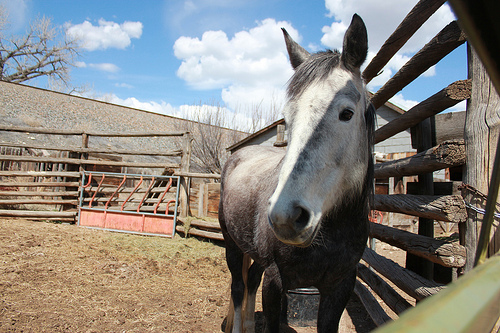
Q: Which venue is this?
A: This is a pen.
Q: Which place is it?
A: It is a pen.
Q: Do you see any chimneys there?
A: No, there are no chimneys.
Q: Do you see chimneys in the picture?
A: No, there are no chimneys.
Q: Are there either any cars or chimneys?
A: No, there are no chimneys or cars.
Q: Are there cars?
A: No, there are no cars.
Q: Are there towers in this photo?
A: No, there are no towers.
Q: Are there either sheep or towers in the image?
A: No, there are no towers or sheep.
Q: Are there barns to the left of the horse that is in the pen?
A: Yes, there is a barn to the left of the horse.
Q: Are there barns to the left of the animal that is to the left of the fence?
A: Yes, there is a barn to the left of the horse.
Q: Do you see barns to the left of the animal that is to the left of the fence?
A: Yes, there is a barn to the left of the horse.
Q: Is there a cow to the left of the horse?
A: No, there is a barn to the left of the horse.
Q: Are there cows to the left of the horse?
A: No, there is a barn to the left of the horse.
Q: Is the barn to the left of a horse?
A: Yes, the barn is to the left of a horse.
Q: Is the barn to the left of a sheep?
A: No, the barn is to the left of a horse.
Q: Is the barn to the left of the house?
A: Yes, the barn is to the left of the house.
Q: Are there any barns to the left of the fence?
A: Yes, there is a barn to the left of the fence.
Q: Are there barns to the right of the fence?
A: No, the barn is to the left of the fence.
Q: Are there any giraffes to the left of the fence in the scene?
A: No, there is a barn to the left of the fence.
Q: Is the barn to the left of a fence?
A: Yes, the barn is to the left of a fence.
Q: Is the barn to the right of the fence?
A: No, the barn is to the left of the fence.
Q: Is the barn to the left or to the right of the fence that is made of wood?
A: The barn is to the left of the fence.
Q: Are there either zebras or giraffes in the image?
A: No, there are no giraffes or zebras.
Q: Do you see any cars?
A: No, there are no cars.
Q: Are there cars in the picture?
A: No, there are no cars.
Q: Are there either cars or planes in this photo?
A: No, there are no cars or planes.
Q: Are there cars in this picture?
A: No, there are no cars.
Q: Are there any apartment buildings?
A: No, there are no apartment buildings.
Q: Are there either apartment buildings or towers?
A: No, there are no apartment buildings or towers.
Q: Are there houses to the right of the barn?
A: Yes, there is a house to the right of the barn.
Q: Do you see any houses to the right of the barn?
A: Yes, there is a house to the right of the barn.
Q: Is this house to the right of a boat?
A: No, the house is to the right of the barn.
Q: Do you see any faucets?
A: No, there are no faucets.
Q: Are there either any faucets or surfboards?
A: No, there are no faucets or surfboards.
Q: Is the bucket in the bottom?
A: Yes, the bucket is in the bottom of the image.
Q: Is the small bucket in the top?
A: No, the bucket is in the bottom of the image.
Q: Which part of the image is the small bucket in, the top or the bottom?
A: The bucket is in the bottom of the image.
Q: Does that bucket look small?
A: Yes, the bucket is small.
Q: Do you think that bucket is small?
A: Yes, the bucket is small.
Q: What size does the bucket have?
A: The bucket has small size.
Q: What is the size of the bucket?
A: The bucket is small.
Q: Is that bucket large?
A: No, the bucket is small.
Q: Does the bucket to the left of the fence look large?
A: No, the bucket is small.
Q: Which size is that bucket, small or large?
A: The bucket is small.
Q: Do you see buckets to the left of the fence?
A: Yes, there is a bucket to the left of the fence.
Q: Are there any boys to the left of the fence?
A: No, there is a bucket to the left of the fence.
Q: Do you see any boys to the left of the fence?
A: No, there is a bucket to the left of the fence.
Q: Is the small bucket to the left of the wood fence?
A: Yes, the bucket is to the left of the fence.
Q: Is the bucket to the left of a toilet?
A: No, the bucket is to the left of the fence.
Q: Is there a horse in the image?
A: Yes, there is a horse.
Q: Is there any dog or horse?
A: Yes, there is a horse.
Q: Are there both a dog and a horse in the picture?
A: No, there is a horse but no dogs.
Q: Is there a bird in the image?
A: No, there are no birds.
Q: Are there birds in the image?
A: No, there are no birds.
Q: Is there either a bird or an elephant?
A: No, there are no birds or elephants.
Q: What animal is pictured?
A: The animal is a horse.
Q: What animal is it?
A: The animal is a horse.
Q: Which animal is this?
A: That is a horse.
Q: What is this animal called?
A: That is a horse.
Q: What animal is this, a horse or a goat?
A: That is a horse.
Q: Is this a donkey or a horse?
A: This is a horse.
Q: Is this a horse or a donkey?
A: This is a horse.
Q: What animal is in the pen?
A: The horse is in the pen.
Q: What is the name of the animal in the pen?
A: The animal is a horse.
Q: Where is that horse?
A: The horse is in the pen.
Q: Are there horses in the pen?
A: Yes, there is a horse in the pen.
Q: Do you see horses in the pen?
A: Yes, there is a horse in the pen.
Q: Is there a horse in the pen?
A: Yes, there is a horse in the pen.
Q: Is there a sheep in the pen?
A: No, there is a horse in the pen.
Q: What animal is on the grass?
A: The horse is on the grass.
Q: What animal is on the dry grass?
A: The animal is a horse.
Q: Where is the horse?
A: The horse is on the grass.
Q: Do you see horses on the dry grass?
A: Yes, there is a horse on the grass.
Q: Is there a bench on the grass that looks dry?
A: No, there is a horse on the grass.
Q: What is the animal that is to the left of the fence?
A: The animal is a horse.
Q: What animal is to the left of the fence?
A: The animal is a horse.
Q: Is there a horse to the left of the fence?
A: Yes, there is a horse to the left of the fence.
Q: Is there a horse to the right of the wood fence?
A: No, the horse is to the left of the fence.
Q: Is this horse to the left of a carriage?
A: No, the horse is to the left of a fence.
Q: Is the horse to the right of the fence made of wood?
A: No, the horse is to the left of the fence.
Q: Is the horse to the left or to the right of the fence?
A: The horse is to the left of the fence.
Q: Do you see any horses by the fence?
A: Yes, there is a horse by the fence.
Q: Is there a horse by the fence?
A: Yes, there is a horse by the fence.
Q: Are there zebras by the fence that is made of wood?
A: No, there is a horse by the fence.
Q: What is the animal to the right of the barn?
A: The animal is a horse.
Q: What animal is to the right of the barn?
A: The animal is a horse.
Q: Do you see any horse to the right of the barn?
A: Yes, there is a horse to the right of the barn.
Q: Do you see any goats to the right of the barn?
A: No, there is a horse to the right of the barn.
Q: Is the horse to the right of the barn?
A: Yes, the horse is to the right of the barn.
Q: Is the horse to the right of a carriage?
A: No, the horse is to the right of the barn.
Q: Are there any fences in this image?
A: Yes, there is a fence.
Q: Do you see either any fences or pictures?
A: Yes, there is a fence.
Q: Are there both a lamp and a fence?
A: No, there is a fence but no lamps.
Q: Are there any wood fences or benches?
A: Yes, there is a wood fence.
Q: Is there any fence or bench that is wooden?
A: Yes, the fence is wooden.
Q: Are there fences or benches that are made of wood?
A: Yes, the fence is made of wood.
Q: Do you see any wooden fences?
A: Yes, there is a wood fence.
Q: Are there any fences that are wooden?
A: Yes, there is a fence that is wooden.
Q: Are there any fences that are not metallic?
A: Yes, there is a wooden fence.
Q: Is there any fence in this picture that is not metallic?
A: Yes, there is a wooden fence.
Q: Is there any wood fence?
A: Yes, there is a fence that is made of wood.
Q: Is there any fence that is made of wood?
A: Yes, there is a fence that is made of wood.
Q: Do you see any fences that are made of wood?
A: Yes, there is a fence that is made of wood.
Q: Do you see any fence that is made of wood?
A: Yes, there is a fence that is made of wood.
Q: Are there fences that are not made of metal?
A: Yes, there is a fence that is made of wood.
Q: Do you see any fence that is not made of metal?
A: Yes, there is a fence that is made of wood.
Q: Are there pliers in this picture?
A: No, there are no pliers.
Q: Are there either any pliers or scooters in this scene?
A: No, there are no pliers or scooters.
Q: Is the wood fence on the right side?
A: Yes, the fence is on the right of the image.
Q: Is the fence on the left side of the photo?
A: No, the fence is on the right of the image.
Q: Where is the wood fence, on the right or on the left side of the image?
A: The fence is on the right of the image.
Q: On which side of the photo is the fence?
A: The fence is on the right of the image.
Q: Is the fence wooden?
A: Yes, the fence is wooden.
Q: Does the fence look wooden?
A: Yes, the fence is wooden.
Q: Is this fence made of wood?
A: Yes, the fence is made of wood.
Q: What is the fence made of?
A: The fence is made of wood.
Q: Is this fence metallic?
A: No, the fence is wooden.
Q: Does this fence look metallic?
A: No, the fence is wooden.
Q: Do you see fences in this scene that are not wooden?
A: No, there is a fence but it is wooden.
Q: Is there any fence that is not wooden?
A: No, there is a fence but it is wooden.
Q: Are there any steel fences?
A: No, there is a fence but it is made of wood.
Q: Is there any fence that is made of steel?
A: No, there is a fence but it is made of wood.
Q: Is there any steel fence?
A: No, there is a fence but it is made of wood.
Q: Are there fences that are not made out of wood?
A: No, there is a fence but it is made of wood.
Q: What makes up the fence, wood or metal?
A: The fence is made of wood.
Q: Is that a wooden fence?
A: Yes, that is a wooden fence.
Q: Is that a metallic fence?
A: No, that is a wooden fence.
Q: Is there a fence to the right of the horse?
A: Yes, there is a fence to the right of the horse.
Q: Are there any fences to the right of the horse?
A: Yes, there is a fence to the right of the horse.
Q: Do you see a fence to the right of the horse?
A: Yes, there is a fence to the right of the horse.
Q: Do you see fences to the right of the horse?
A: Yes, there is a fence to the right of the horse.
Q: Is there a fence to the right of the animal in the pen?
A: Yes, there is a fence to the right of the horse.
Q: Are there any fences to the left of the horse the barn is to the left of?
A: No, the fence is to the right of the horse.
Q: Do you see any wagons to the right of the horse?
A: No, there is a fence to the right of the horse.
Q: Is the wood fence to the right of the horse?
A: Yes, the fence is to the right of the horse.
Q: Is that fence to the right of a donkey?
A: No, the fence is to the right of the horse.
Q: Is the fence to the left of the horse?
A: No, the fence is to the right of the horse.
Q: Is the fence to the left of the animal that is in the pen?
A: No, the fence is to the right of the horse.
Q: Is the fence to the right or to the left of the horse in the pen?
A: The fence is to the right of the horse.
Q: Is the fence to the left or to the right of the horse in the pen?
A: The fence is to the right of the horse.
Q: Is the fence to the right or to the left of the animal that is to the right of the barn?
A: The fence is to the right of the horse.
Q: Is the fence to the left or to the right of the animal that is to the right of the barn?
A: The fence is to the right of the horse.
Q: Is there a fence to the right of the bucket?
A: Yes, there is a fence to the right of the bucket.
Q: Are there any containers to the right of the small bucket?
A: No, there is a fence to the right of the bucket.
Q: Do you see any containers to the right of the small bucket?
A: No, there is a fence to the right of the bucket.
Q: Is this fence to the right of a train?
A: No, the fence is to the right of the bucket.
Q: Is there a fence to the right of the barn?
A: Yes, there is a fence to the right of the barn.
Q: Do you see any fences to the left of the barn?
A: No, the fence is to the right of the barn.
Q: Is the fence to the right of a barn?
A: Yes, the fence is to the right of a barn.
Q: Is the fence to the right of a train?
A: No, the fence is to the right of a barn.